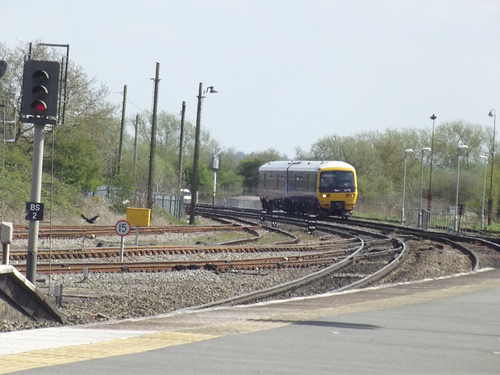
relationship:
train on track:
[257, 160, 357, 220] [328, 209, 471, 297]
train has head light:
[257, 160, 357, 220] [317, 188, 334, 201]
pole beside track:
[190, 83, 207, 222] [6, 198, 213, 261]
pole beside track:
[179, 101, 186, 223] [328, 209, 471, 297]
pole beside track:
[146, 63, 157, 209] [6, 198, 213, 261]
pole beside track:
[131, 116, 145, 174] [6, 198, 213, 261]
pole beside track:
[114, 85, 126, 181] [6, 198, 213, 261]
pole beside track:
[399, 147, 413, 225] [328, 209, 471, 297]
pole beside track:
[417, 146, 431, 225] [328, 209, 471, 297]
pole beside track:
[450, 144, 464, 235] [328, 209, 471, 297]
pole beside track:
[209, 153, 221, 209] [6, 198, 213, 261]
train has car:
[257, 160, 357, 220] [287, 152, 357, 216]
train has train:
[257, 160, 357, 220] [257, 160, 357, 220]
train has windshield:
[257, 160, 357, 220] [320, 170, 350, 196]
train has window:
[257, 160, 357, 220] [295, 175, 301, 179]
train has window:
[257, 160, 357, 220] [267, 171, 275, 179]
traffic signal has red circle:
[17, 56, 60, 132] [33, 101, 50, 112]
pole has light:
[190, 83, 207, 222] [203, 81, 218, 95]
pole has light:
[399, 147, 413, 225] [404, 147, 415, 157]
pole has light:
[417, 146, 431, 225] [419, 144, 436, 157]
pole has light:
[450, 144, 464, 235] [456, 138, 468, 155]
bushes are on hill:
[12, 143, 99, 213] [4, 146, 112, 221]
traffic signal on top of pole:
[17, 56, 60, 132] [21, 124, 48, 283]